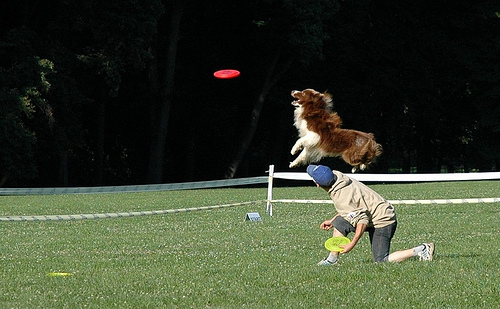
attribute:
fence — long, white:
[5, 160, 496, 229]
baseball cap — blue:
[301, 159, 337, 187]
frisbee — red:
[209, 64, 245, 84]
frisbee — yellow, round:
[322, 232, 355, 254]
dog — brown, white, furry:
[276, 83, 385, 173]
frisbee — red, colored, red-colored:
[207, 63, 242, 81]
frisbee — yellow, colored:
[207, 65, 242, 83]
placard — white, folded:
[242, 207, 270, 219]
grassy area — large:
[3, 171, 497, 307]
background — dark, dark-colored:
[0, 0, 493, 190]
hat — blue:
[303, 158, 336, 188]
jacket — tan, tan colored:
[319, 176, 401, 231]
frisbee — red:
[213, 68, 241, 78]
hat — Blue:
[304, 161, 335, 185]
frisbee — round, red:
[213, 67, 242, 79]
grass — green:
[0, 178, 498, 305]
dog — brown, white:
[288, 86, 381, 171]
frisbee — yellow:
[46, 268, 71, 277]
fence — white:
[3, 160, 498, 222]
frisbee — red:
[212, 69, 242, 79]